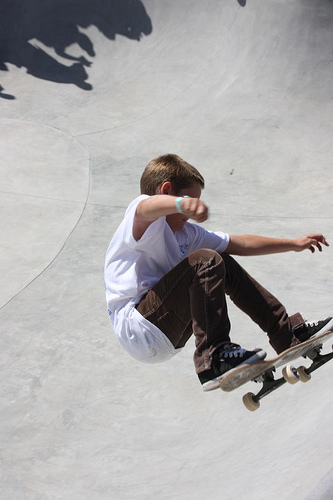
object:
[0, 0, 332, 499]
skate bowl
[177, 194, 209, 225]
hand/boy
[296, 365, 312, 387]
wheel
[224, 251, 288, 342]
leg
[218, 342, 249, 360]
laces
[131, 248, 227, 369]
leg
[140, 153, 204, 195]
hair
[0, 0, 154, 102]
shadows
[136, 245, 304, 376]
pants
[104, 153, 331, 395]
boy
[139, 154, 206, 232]
head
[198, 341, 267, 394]
shoe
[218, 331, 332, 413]
skate board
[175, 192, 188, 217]
blue band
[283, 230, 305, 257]
wrist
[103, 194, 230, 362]
t-shirt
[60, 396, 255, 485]
cement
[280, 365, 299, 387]
wheels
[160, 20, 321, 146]
air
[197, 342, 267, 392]
foot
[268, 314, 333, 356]
shoe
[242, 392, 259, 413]
wheel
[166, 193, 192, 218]
wrist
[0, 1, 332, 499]
skate ramp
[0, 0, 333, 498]
ground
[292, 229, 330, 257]
hand